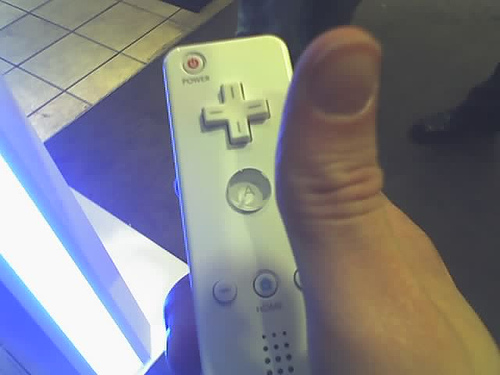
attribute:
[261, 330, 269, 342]
dot — Small , black 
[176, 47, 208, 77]
button — round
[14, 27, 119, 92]
tile — square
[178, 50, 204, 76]
button — small 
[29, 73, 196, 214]
rug — dark 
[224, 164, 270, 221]
button — white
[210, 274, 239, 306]
button — white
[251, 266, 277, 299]
button — white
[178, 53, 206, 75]
button — white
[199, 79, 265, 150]
button — white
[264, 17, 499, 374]
thumb — upright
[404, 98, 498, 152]
black shoe — black 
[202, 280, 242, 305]
controller button — white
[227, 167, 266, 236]
button — minus sign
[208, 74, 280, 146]
button — cross shaped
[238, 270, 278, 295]
house — small , blue 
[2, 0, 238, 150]
floor — tiled, white, tile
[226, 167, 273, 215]
button — clear , plastic 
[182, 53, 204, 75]
button — red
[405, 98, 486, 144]
foot — resting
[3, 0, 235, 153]
tile floor — white 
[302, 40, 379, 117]
nail — thumb 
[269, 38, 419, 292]
finger — partially visible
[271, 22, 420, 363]
thumb — fully visible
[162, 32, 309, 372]
wii remote — white, plastic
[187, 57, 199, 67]
symbol — red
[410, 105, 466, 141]
shoe — black 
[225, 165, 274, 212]
button — missing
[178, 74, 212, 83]
word — power 